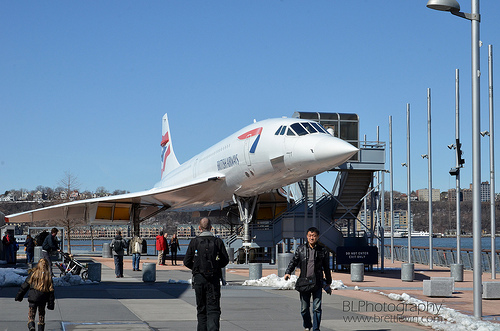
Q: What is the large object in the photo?
A: A plane.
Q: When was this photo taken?
A: Day time.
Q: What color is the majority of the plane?
A: White.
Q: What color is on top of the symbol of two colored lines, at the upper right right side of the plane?
A: Red.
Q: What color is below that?
A: Blue.